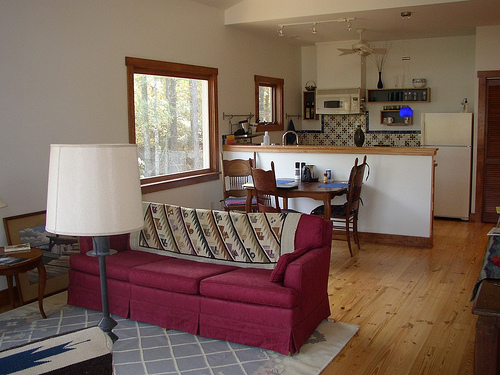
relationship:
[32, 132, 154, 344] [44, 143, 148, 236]
lamp has lamp shade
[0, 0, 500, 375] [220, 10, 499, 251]
house and kitchen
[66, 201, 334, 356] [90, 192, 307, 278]
couch with blanket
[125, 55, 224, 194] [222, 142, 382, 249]
window in dining area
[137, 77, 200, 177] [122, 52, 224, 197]
trees outside window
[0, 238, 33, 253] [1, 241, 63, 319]
book on table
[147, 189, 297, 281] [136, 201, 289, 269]
pattern on blanket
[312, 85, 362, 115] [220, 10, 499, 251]
microwave in kitchen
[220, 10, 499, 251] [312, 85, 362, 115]
kitchen has microwave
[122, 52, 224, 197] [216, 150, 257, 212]
window near chair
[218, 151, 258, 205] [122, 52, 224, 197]
brown chair near window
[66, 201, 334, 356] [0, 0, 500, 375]
couch in house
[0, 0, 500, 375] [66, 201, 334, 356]
house has couch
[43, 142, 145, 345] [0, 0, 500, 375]
lamp in house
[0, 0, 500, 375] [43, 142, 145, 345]
house has lamp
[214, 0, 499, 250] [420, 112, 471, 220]
kitchen has refrigerator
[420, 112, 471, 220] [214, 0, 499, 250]
refrigerator in kitchen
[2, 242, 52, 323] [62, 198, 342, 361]
end table near sofa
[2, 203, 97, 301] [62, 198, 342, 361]
picture frame near sofa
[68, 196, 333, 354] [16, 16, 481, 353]
couch in house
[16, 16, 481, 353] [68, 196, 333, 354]
house has couch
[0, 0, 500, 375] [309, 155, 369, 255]
house has chair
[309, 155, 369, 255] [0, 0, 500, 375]
chair in house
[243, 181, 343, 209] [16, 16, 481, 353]
table in house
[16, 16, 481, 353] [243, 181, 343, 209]
house has table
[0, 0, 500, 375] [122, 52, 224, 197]
house has window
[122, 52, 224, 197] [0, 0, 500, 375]
window in house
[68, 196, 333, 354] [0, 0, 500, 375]
couch in house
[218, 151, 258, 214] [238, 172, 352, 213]
brown chair at table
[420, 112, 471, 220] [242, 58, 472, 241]
refrigerator in kitchen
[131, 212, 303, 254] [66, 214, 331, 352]
blanket on couch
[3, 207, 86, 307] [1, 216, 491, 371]
painting on floor